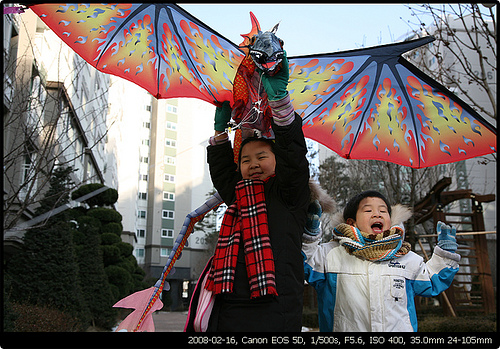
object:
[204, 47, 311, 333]
child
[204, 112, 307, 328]
coat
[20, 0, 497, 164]
kite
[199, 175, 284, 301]
scarf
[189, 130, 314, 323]
jacket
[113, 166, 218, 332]
tail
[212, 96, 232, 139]
glove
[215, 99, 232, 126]
hand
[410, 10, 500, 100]
tree branches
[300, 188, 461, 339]
child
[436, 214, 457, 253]
blue gloves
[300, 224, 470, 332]
blue and white coat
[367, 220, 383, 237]
open mouth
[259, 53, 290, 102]
green gloves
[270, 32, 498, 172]
wings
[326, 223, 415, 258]
scarf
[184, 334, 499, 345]
picture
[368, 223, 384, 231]
mouth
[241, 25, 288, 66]
head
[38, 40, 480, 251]
scene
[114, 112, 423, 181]
image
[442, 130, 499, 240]
downtown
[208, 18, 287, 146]
dragon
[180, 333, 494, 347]
watermark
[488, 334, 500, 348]
corner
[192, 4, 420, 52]
sky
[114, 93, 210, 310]
buildings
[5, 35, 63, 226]
trees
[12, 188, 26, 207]
left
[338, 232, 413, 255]
boy neck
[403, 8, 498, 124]
tree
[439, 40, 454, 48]
no leaves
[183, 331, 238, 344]
date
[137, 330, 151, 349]
bottom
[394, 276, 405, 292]
writing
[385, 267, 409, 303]
pocket